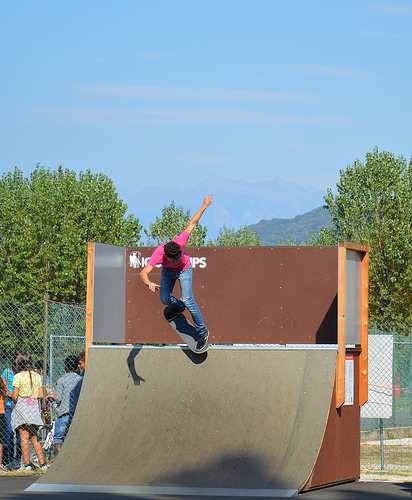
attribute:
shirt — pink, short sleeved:
[148, 234, 193, 274]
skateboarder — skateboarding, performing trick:
[136, 190, 220, 359]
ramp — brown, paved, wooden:
[25, 238, 373, 498]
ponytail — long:
[14, 346, 41, 391]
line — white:
[25, 473, 301, 499]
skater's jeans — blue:
[154, 266, 210, 343]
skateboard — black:
[161, 304, 211, 356]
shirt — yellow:
[9, 366, 43, 398]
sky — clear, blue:
[0, 1, 412, 248]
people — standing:
[2, 353, 85, 473]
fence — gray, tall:
[0, 296, 411, 480]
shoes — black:
[162, 304, 209, 351]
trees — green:
[2, 148, 412, 373]